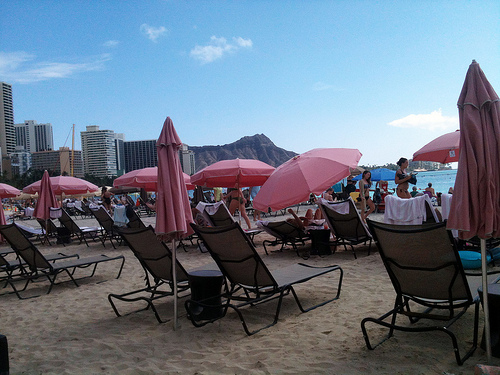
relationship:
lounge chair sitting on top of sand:
[191, 219, 345, 335] [0, 237, 498, 371]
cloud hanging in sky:
[185, 43, 233, 66] [2, 2, 483, 167]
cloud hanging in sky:
[204, 34, 227, 46] [2, 2, 483, 167]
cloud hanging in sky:
[232, 36, 254, 49] [2, 2, 483, 167]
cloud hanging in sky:
[133, 19, 171, 43] [2, 2, 483, 167]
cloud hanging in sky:
[0, 39, 123, 84] [2, 2, 483, 167]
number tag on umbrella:
[446, 149, 456, 159] [413, 125, 467, 165]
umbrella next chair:
[151, 117, 188, 337] [192, 219, 343, 337]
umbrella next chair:
[151, 117, 188, 337] [102, 222, 220, 329]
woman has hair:
[389, 158, 419, 195] [395, 156, 405, 170]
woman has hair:
[353, 167, 374, 215] [359, 164, 379, 191]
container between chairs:
[188, 253, 232, 330] [86, 179, 347, 340]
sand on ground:
[5, 202, 497, 372] [35, 323, 235, 372]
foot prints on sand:
[242, 332, 311, 364] [44, 312, 89, 350]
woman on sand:
[393, 156, 419, 200] [5, 202, 497, 372]